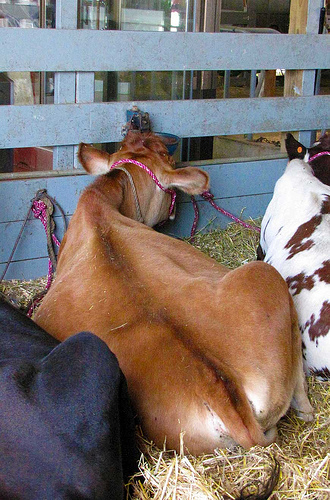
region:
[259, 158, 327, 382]
a white cow with brown spots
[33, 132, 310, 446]
a brown cow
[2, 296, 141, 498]
a black cow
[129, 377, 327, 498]
straw underneath cows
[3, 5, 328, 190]
a pale blue fence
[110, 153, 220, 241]
a purple rope on a cow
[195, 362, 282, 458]
the tail of a brown cow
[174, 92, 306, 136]
a dirt spattered blue board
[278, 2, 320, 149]
a wooden post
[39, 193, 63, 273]
a dirty brown rope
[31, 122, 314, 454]
The middle brown cow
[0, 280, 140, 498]
The black cow next to the brown one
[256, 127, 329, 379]
The brown and white cow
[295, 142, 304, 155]
The orange tag on a cow's ear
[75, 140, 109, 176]
The brown cow's left ear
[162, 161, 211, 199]
The right ear of the brown cow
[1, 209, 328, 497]
The hay the cows are on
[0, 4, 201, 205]
The windows in the background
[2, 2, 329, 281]
The blue fence the coes are tied to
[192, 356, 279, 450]
The tail of the brown cow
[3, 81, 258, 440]
cattle in an enclosed pen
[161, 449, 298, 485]
yellow and white straw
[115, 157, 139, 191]
A rope tied around an animals neck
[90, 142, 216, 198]
head of a cow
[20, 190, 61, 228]
Some rope tied to a wooden structure.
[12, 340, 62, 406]
black fur of a animal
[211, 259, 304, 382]
Tanned fur of a hind quarter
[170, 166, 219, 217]
Tan and white fur of a cow's ear.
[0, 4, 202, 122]
A glass window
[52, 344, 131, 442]
black furred hind quarter of a cow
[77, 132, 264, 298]
the cow has a purple rope around it's neck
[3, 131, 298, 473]
the cow is brown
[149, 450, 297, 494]
the cows are laying in straw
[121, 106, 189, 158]
a blue bowl is on the wall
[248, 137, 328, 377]
this cow is brown & white speckled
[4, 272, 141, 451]
this cow is black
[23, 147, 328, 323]
all the cows are tied together with the purple rope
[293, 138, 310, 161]
this cow has an orange sticker on its ear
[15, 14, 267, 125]
the stall is grey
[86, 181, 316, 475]
the cow has a darker stripe down the center of it's back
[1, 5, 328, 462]
a place to store livestock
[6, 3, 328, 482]
three animals are lying here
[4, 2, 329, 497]
a scene inside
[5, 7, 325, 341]
a blue fence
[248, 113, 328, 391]
a white cow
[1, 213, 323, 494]
some tan hay here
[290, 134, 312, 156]
an orange tag on ear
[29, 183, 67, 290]
a purple rope here